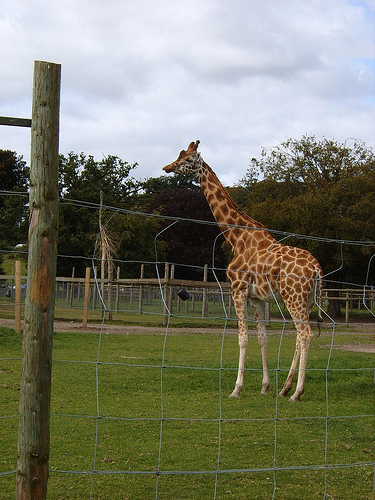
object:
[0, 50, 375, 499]
enclosure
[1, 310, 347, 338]
dirt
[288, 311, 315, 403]
leg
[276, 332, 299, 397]
leg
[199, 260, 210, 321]
fencing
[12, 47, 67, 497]
post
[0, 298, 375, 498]
foreground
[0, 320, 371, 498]
grassland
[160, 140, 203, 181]
head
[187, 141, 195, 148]
horn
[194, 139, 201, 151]
horn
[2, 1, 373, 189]
clouds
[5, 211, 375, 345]
structure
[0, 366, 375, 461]
dirt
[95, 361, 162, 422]
gaps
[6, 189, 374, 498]
fence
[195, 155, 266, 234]
mane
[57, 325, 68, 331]
dirt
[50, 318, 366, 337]
path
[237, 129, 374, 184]
tree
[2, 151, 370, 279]
treeline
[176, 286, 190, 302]
barrel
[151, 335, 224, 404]
grass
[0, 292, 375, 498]
surface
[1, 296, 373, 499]
ground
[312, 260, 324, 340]
tail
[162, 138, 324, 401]
giraffe